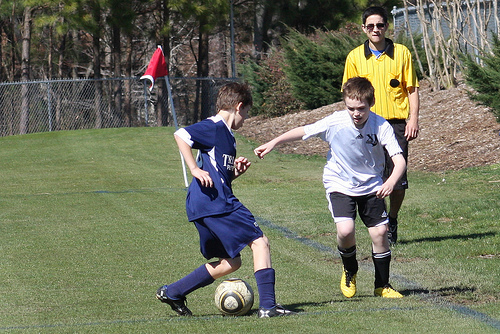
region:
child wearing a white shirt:
[310, 106, 408, 195]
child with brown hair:
[329, 68, 386, 130]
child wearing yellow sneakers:
[327, 256, 367, 301]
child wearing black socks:
[333, 235, 355, 285]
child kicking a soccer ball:
[213, 273, 262, 330]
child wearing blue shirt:
[169, 109, 251, 206]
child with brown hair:
[209, 81, 261, 123]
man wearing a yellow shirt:
[341, 48, 421, 120]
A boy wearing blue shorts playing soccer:
[150, 70, 297, 325]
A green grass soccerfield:
[11, 137, 153, 332]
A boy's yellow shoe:
[362, 275, 407, 304]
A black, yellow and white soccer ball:
[202, 266, 266, 319]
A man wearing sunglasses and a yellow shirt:
[327, 5, 475, 151]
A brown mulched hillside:
[432, 96, 478, 161]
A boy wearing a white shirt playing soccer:
[252, 71, 454, 314]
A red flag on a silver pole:
[132, 40, 192, 111]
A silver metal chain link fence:
[6, 67, 121, 132]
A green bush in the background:
[265, 18, 360, 110]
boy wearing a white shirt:
[277, 78, 407, 300]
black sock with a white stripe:
[371, 248, 393, 283]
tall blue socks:
[160, 262, 275, 310]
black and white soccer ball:
[213, 278, 257, 315]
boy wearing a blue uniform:
[165, 85, 282, 315]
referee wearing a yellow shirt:
[340, 6, 418, 181]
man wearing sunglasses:
[357, 3, 390, 40]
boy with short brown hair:
[339, 76, 376, 122]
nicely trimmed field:
[1, 145, 113, 330]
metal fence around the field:
[4, 76, 171, 131]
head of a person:
[212, 82, 257, 133]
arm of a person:
[169, 120, 205, 167]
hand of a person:
[185, 168, 215, 180]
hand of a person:
[232, 146, 254, 174]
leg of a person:
[243, 213, 287, 313]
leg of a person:
[171, 225, 238, 294]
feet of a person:
[150, 294, 202, 319]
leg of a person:
[326, 200, 357, 275]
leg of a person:
[357, 208, 408, 277]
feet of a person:
[328, 270, 364, 301]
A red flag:
[151, 57, 163, 73]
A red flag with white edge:
[146, 73, 156, 77]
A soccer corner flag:
[152, 59, 164, 74]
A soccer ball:
[221, 285, 246, 310]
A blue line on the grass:
[292, 233, 298, 239]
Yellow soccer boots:
[343, 286, 353, 295]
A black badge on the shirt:
[392, 79, 397, 86]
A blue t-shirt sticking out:
[375, 51, 380, 55]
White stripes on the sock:
[375, 254, 385, 256]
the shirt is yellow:
[341, 36, 418, 120]